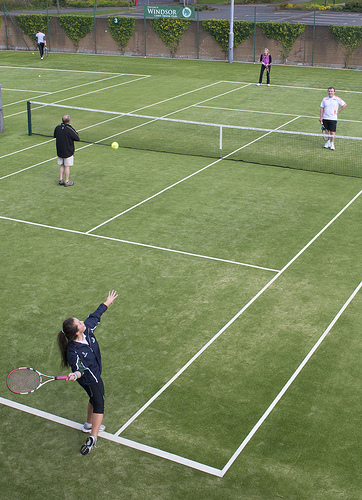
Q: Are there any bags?
A: No, there are no bags.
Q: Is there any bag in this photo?
A: No, there are no bags.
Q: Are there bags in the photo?
A: No, there are no bags.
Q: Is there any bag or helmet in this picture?
A: No, there are no bags or helmets.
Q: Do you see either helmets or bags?
A: No, there are no bags or helmets.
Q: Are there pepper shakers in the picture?
A: No, there are no pepper shakers.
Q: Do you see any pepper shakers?
A: No, there are no pepper shakers.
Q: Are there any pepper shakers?
A: No, there are no pepper shakers.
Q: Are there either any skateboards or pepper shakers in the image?
A: No, there are no pepper shakers or skateboards.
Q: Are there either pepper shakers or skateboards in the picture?
A: No, there are no pepper shakers or skateboards.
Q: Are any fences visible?
A: Yes, there is a fence.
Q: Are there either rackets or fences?
A: Yes, there is a fence.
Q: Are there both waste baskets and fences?
A: No, there is a fence but no waste baskets.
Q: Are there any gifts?
A: No, there are no gifts.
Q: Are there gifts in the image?
A: No, there are no gifts.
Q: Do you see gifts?
A: No, there are no gifts.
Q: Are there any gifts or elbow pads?
A: No, there are no gifts or elbow pads.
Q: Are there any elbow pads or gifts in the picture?
A: No, there are no gifts or elbow pads.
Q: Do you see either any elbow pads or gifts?
A: No, there are no gifts or elbow pads.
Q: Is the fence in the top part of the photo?
A: Yes, the fence is in the top of the image.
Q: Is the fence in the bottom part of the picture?
A: No, the fence is in the top of the image.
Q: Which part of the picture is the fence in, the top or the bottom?
A: The fence is in the top of the image.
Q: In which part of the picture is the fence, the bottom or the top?
A: The fence is in the top of the image.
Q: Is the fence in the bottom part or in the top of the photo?
A: The fence is in the top of the image.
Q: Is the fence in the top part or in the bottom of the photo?
A: The fence is in the top of the image.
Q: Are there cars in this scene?
A: No, there are no cars.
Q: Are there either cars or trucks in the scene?
A: No, there are no cars or trucks.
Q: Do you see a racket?
A: Yes, there is a racket.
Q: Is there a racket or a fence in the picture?
A: Yes, there is a racket.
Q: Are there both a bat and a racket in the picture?
A: No, there is a racket but no bats.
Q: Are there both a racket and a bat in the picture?
A: No, there is a racket but no bats.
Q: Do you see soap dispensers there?
A: No, there are no soap dispensers.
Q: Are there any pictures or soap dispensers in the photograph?
A: No, there are no soap dispensers or pictures.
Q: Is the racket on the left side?
A: Yes, the racket is on the left of the image.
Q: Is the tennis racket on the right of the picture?
A: No, the tennis racket is on the left of the image.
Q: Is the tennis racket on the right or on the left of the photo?
A: The tennis racket is on the left of the image.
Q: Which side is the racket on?
A: The racket is on the left of the image.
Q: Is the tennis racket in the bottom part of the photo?
A: Yes, the tennis racket is in the bottom of the image.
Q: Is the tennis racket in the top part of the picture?
A: No, the tennis racket is in the bottom of the image.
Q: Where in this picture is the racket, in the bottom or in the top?
A: The racket is in the bottom of the image.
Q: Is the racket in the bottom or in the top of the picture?
A: The racket is in the bottom of the image.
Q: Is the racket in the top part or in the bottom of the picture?
A: The racket is in the bottom of the image.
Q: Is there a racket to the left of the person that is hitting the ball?
A: Yes, there is a racket to the left of the person.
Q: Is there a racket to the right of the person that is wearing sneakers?
A: No, the racket is to the left of the person.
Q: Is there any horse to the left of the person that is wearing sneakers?
A: No, there is a racket to the left of the person.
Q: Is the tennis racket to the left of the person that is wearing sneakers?
A: Yes, the tennis racket is to the left of the person.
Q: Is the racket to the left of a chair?
A: No, the racket is to the left of the person.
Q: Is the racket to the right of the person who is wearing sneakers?
A: No, the racket is to the left of the person.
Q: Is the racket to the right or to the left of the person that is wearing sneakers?
A: The racket is to the left of the person.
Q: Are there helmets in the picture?
A: No, there are no helmets.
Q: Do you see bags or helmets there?
A: No, there are no helmets or bags.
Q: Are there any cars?
A: No, there are no cars.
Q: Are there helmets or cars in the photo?
A: No, there are no cars or helmets.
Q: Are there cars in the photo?
A: No, there are no cars.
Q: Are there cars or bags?
A: No, there are no cars or bags.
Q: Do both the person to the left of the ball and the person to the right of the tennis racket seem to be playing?
A: Yes, both the person and the person are playing.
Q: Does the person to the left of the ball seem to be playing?
A: Yes, the person is playing.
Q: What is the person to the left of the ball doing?
A: The person is playing.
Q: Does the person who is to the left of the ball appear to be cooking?
A: No, the person is playing.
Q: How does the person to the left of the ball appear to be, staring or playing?
A: The person is playing.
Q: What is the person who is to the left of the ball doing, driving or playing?
A: The person is playing.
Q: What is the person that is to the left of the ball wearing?
A: The person is wearing shorts.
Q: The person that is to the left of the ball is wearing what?
A: The person is wearing shorts.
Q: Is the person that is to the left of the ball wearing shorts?
A: Yes, the person is wearing shorts.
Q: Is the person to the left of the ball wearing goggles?
A: No, the person is wearing shorts.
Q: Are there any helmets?
A: No, there are no helmets.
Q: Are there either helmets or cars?
A: No, there are no helmets or cars.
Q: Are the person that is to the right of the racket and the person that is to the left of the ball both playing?
A: Yes, both the person and the person are playing.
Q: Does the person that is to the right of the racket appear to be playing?
A: Yes, the person is playing.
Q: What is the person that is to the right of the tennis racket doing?
A: The person is playing.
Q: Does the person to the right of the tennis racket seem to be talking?
A: No, the person is playing.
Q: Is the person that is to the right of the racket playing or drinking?
A: The person is playing.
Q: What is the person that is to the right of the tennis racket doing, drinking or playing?
A: The person is playing.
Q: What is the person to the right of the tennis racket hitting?
A: The person is hitting the ball.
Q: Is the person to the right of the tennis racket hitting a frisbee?
A: No, the person is hitting the ball.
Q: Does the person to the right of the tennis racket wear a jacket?
A: Yes, the person wears a jacket.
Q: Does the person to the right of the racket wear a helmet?
A: No, the person wears a jacket.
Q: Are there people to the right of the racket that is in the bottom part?
A: Yes, there is a person to the right of the racket.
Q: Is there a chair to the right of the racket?
A: No, there is a person to the right of the racket.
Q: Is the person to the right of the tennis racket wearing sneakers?
A: Yes, the person is wearing sneakers.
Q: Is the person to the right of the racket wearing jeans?
A: No, the person is wearing sneakers.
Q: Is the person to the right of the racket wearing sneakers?
A: Yes, the person is wearing sneakers.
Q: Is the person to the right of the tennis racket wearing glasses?
A: No, the person is wearing sneakers.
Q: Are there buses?
A: No, there are no buses.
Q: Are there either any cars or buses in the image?
A: No, there are no buses or cars.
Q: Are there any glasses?
A: No, there are no glasses.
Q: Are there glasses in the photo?
A: No, there are no glasses.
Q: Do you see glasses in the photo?
A: No, there are no glasses.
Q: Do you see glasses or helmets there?
A: No, there are no glasses or helmets.